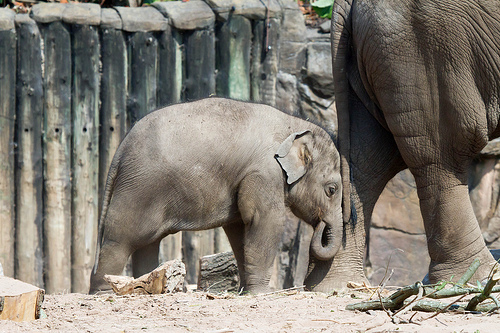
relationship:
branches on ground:
[342, 252, 499, 313] [7, 275, 495, 333]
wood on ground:
[2, 279, 47, 322] [7, 275, 495, 333]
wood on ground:
[102, 257, 189, 296] [7, 275, 495, 333]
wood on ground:
[197, 249, 242, 293] [7, 275, 495, 333]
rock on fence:
[31, 4, 104, 25] [2, 4, 262, 293]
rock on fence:
[103, 6, 166, 33] [2, 4, 262, 293]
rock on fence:
[150, 0, 215, 27] [2, 4, 262, 293]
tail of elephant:
[89, 128, 133, 274] [88, 96, 346, 294]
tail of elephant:
[329, 4, 356, 226] [332, 0, 500, 302]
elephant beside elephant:
[88, 96, 346, 294] [332, 0, 500, 302]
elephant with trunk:
[88, 96, 346, 294] [308, 215, 346, 262]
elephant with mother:
[88, 96, 346, 294] [332, 0, 500, 302]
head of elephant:
[285, 115, 349, 259] [88, 96, 346, 294]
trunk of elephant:
[308, 215, 346, 262] [88, 96, 346, 294]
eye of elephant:
[324, 183, 339, 196] [88, 96, 346, 294]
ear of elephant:
[274, 128, 319, 188] [88, 96, 346, 294]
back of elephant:
[131, 95, 322, 127] [88, 96, 346, 294]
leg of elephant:
[244, 175, 281, 296] [88, 96, 346, 294]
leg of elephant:
[222, 225, 247, 294] [88, 96, 346, 294]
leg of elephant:
[86, 162, 169, 292] [88, 96, 346, 294]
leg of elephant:
[131, 238, 165, 275] [88, 96, 346, 294]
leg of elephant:
[376, 66, 499, 294] [332, 0, 500, 302]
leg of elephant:
[302, 89, 409, 290] [332, 0, 500, 302]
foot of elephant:
[431, 259, 500, 291] [332, 0, 500, 302]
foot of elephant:
[306, 264, 374, 290] [332, 0, 500, 302]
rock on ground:
[31, 4, 104, 25] [7, 275, 495, 333]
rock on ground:
[103, 6, 166, 33] [7, 275, 495, 333]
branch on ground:
[422, 259, 500, 296] [7, 275, 495, 333]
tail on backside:
[89, 128, 133, 274] [109, 117, 165, 174]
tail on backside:
[329, 4, 356, 226] [348, 3, 452, 112]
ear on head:
[274, 128, 319, 188] [285, 115, 349, 259]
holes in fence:
[22, 126, 116, 136] [2, 4, 262, 293]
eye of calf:
[324, 183, 339, 196] [88, 96, 346, 294]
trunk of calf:
[308, 215, 346, 262] [88, 96, 346, 294]